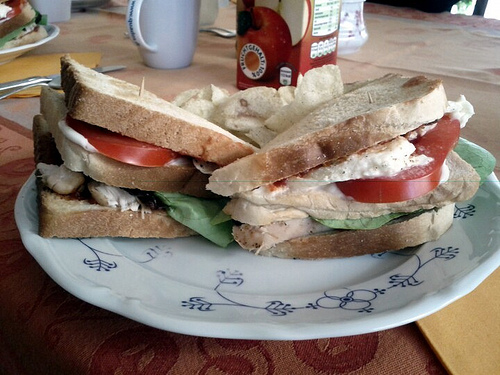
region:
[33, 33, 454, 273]
the sandwiches on the plate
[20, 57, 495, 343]
the plate is white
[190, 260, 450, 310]
the blue design on the plate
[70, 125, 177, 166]
the lettuce in the sandwich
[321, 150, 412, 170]
the mayonnaise in the sandwich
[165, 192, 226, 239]
the lettuce in the sandwich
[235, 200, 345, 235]
the chicken in the sandwich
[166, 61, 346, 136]
the potato chips on the plate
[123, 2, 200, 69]
the white cup on the table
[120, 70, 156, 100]
the toothpick in the sandwich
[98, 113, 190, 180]
red tomotoe on sandwich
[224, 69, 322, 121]
yellow potatoe chips between sandwich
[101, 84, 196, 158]
brown crust on bread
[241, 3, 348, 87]
apple juice in a box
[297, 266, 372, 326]
blue circles on white plate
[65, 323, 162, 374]
table place mat under plate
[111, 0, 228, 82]
white coffee cup with blue design on handle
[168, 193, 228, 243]
green lettuce on sandwich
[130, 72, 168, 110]
light brown wooden toothpick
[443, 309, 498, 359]
light brown wooden table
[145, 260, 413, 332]
this is the plate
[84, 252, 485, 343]
the plate is round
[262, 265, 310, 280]
the plate is white in color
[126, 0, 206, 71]
this is a cup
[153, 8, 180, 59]
the cup is white in color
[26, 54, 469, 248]
these are slices of bread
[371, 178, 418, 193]
this is a tomato slice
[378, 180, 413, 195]
the tomato is red in color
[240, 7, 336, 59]
this is a box of juice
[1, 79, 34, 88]
this is a fork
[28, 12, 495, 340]
A club sandwich and chips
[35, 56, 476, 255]
A toasted sandwich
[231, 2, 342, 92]
A carton of apple juice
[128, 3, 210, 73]
A white coffee cup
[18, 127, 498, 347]
A white plate with a blue design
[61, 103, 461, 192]
Tomato slices on a sandwich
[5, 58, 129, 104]
A case knife laying on the table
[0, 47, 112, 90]
A yellow napkin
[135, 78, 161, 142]
A toothpick in the sandwich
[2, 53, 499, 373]
A plate of food sitting on a table cloth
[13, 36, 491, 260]
tall sandwich on white bread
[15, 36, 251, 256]
half of a sandwich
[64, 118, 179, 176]
slice of tomato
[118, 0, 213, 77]
white ceramic mug with lettering on handle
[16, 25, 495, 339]
sandwich and chips on plate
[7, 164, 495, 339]
white ceramic plate with blue design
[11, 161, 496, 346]
large plate with blue swirly design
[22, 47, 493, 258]
sandwich with meat and veggies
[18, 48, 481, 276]
sandwich with mayonnaise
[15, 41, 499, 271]
sandwich and potato chips